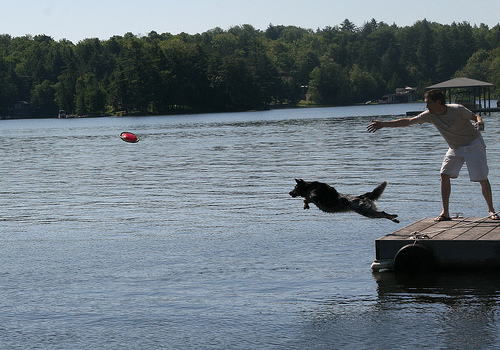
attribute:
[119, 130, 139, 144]
frisbee — flying, red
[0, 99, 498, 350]
lake — calm, beautiful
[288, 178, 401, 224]
dog — jumping, black, airborne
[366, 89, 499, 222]
man — throwing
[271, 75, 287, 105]
tree — pine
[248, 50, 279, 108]
tree — pine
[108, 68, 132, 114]
tree — pine, green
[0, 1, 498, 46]
sky — pale, blue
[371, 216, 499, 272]
dock — wooden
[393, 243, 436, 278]
tire — tie